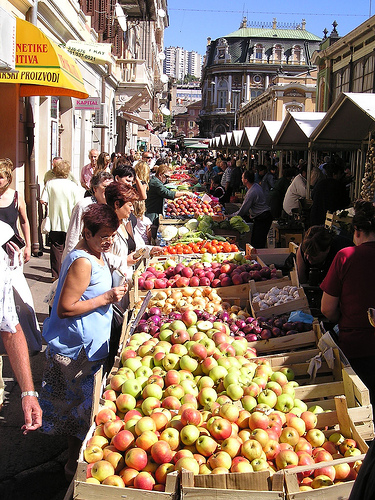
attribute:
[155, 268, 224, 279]
red apples — round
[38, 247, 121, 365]
tank top — blue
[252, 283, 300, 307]
white onions — round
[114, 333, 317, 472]
apple — red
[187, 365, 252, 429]
apple — round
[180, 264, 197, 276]
apple — red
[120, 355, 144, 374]
green apple — round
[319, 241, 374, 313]
shirt — red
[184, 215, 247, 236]
lettuce heads — round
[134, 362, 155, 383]
apple — green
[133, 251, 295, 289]
apples — round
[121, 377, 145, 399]
apple — green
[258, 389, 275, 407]
apple — green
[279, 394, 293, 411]
apple — green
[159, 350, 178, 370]
apple — green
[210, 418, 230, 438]
apple — green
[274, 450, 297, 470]
apple — green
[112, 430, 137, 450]
apple — green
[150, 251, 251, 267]
aples — round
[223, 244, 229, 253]
tomatoes — round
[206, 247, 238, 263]
apple — round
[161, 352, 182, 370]
apple — green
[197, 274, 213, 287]
apple — red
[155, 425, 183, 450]
apple — green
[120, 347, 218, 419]
apple — round